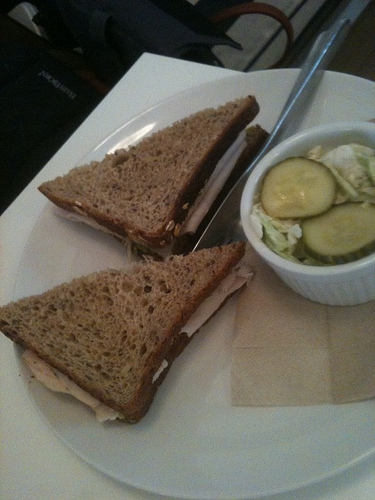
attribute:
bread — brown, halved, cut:
[0, 238, 247, 415]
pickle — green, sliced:
[259, 156, 338, 220]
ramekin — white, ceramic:
[239, 121, 374, 306]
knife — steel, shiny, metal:
[192, 17, 353, 253]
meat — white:
[178, 261, 255, 336]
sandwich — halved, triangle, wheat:
[2, 95, 270, 424]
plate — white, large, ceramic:
[13, 68, 375, 500]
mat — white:
[0, 51, 373, 498]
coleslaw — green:
[248, 143, 374, 267]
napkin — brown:
[228, 238, 374, 406]